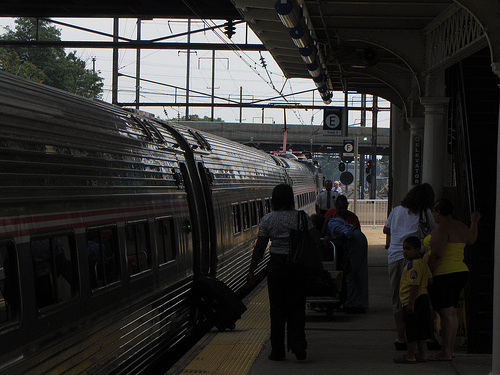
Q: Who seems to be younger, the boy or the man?
A: The boy is younger than the man.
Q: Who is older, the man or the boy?
A: The man is older than the boy.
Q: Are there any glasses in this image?
A: No, there are no glasses.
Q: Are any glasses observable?
A: No, there are no glasses.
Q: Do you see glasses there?
A: No, there are no glasses.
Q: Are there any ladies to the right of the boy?
A: Yes, there is a lady to the right of the boy.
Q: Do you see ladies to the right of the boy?
A: Yes, there is a lady to the right of the boy.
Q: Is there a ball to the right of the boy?
A: No, there is a lady to the right of the boy.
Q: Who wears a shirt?
A: The lady wears a shirt.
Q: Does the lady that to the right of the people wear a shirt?
A: Yes, the lady wears a shirt.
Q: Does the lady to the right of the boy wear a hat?
A: No, the lady wears a shirt.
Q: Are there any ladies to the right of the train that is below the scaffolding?
A: Yes, there is a lady to the right of the train.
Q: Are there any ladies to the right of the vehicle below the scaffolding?
A: Yes, there is a lady to the right of the train.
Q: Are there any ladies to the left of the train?
A: No, the lady is to the right of the train.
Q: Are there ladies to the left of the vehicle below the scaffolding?
A: No, the lady is to the right of the train.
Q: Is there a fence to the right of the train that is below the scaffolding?
A: No, there is a lady to the right of the train.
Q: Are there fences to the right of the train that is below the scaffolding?
A: No, there is a lady to the right of the train.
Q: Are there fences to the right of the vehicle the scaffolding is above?
A: No, there is a lady to the right of the train.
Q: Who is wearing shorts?
A: The lady is wearing shorts.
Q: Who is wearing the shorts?
A: The lady is wearing shorts.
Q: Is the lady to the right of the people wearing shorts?
A: Yes, the lady is wearing shorts.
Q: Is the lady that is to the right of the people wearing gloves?
A: No, the lady is wearing shorts.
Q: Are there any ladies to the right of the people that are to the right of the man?
A: Yes, there is a lady to the right of the people.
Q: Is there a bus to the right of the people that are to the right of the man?
A: No, there is a lady to the right of the people.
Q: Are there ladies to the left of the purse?
A: No, the lady is to the right of the purse.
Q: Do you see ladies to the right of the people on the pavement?
A: Yes, there is a lady to the right of the people.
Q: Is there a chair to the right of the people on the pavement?
A: No, there is a lady to the right of the people.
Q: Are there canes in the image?
A: No, there are no canes.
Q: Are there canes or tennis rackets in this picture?
A: No, there are no canes or tennis rackets.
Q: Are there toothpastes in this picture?
A: No, there are no toothpastes.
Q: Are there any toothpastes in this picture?
A: No, there are no toothpastes.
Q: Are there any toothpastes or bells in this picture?
A: No, there are no toothpastes or bells.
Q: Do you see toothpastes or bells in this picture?
A: No, there are no toothpastes or bells.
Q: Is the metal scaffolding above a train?
A: Yes, the scaffolding is above a train.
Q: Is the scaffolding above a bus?
A: No, the scaffolding is above a train.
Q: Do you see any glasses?
A: No, there are no glasses.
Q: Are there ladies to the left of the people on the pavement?
A: Yes, there is a lady to the left of the people.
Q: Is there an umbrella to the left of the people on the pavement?
A: No, there is a lady to the left of the people.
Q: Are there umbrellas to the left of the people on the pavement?
A: No, there is a lady to the left of the people.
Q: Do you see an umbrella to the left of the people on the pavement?
A: No, there is a lady to the left of the people.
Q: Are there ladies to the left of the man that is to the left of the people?
A: Yes, there is a lady to the left of the man.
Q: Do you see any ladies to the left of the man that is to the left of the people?
A: Yes, there is a lady to the left of the man.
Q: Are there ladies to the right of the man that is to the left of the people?
A: No, the lady is to the left of the man.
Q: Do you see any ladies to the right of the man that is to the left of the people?
A: No, the lady is to the left of the man.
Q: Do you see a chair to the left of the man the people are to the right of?
A: No, there is a lady to the left of the man.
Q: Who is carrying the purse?
A: The lady is carrying the purse.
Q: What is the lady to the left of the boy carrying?
A: The lady is carrying a purse.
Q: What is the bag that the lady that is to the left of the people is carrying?
A: The bag is a purse.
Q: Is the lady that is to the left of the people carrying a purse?
A: Yes, the lady is carrying a purse.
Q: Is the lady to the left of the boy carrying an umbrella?
A: No, the lady is carrying a purse.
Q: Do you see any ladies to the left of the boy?
A: Yes, there is a lady to the left of the boy.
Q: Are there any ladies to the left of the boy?
A: Yes, there is a lady to the left of the boy.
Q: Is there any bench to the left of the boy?
A: No, there is a lady to the left of the boy.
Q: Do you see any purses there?
A: Yes, there is a purse.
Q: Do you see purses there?
A: Yes, there is a purse.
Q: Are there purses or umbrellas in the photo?
A: Yes, there is a purse.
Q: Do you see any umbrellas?
A: No, there are no umbrellas.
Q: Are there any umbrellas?
A: No, there are no umbrellas.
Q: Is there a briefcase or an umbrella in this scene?
A: No, there are no umbrellas or briefcases.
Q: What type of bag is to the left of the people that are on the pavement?
A: The bag is a purse.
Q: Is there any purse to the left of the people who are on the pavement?
A: Yes, there is a purse to the left of the people.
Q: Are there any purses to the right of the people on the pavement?
A: No, the purse is to the left of the people.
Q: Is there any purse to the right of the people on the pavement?
A: No, the purse is to the left of the people.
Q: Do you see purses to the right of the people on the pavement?
A: No, the purse is to the left of the people.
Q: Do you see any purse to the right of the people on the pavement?
A: No, the purse is to the left of the people.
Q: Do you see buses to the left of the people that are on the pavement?
A: No, there is a purse to the left of the people.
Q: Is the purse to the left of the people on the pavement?
A: Yes, the purse is to the left of the people.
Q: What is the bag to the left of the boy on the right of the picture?
A: The bag is a purse.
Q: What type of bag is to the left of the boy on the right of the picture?
A: The bag is a purse.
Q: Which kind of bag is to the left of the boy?
A: The bag is a purse.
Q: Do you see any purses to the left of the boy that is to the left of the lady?
A: Yes, there is a purse to the left of the boy.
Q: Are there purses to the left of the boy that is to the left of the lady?
A: Yes, there is a purse to the left of the boy.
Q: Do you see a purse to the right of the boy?
A: No, the purse is to the left of the boy.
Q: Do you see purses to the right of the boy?
A: No, the purse is to the left of the boy.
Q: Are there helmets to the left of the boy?
A: No, there is a purse to the left of the boy.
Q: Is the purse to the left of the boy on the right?
A: Yes, the purse is to the left of the boy.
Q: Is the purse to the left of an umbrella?
A: No, the purse is to the left of the boy.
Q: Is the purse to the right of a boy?
A: No, the purse is to the left of a boy.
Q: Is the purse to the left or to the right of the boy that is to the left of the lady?
A: The purse is to the left of the boy.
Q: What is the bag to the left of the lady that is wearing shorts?
A: The bag is a purse.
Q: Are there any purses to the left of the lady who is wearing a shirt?
A: Yes, there is a purse to the left of the lady.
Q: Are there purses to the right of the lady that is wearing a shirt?
A: No, the purse is to the left of the lady.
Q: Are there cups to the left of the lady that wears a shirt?
A: No, there is a purse to the left of the lady.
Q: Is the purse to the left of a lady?
A: Yes, the purse is to the left of a lady.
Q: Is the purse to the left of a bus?
A: No, the purse is to the left of a lady.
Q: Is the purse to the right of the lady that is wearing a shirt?
A: No, the purse is to the left of the lady.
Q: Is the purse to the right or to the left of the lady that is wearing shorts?
A: The purse is to the left of the lady.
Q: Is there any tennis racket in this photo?
A: No, there are no rackets.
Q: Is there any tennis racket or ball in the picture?
A: No, there are no rackets or balls.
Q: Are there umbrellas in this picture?
A: No, there are no umbrellas.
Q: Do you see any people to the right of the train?
A: Yes, there are people to the right of the train.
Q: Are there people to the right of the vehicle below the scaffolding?
A: Yes, there are people to the right of the train.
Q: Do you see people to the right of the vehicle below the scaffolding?
A: Yes, there are people to the right of the train.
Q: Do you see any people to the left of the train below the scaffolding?
A: No, the people are to the right of the train.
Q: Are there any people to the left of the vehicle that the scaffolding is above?
A: No, the people are to the right of the train.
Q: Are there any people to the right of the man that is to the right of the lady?
A: Yes, there are people to the right of the man.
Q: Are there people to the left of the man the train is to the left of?
A: No, the people are to the right of the man.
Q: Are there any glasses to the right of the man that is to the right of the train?
A: No, there are people to the right of the man.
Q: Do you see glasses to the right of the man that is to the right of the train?
A: No, there are people to the right of the man.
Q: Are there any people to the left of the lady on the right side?
A: Yes, there are people to the left of the lady.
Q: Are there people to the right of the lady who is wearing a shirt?
A: No, the people are to the left of the lady.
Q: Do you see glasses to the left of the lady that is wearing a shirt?
A: No, there are people to the left of the lady.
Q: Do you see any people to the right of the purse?
A: Yes, there are people to the right of the purse.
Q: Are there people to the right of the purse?
A: Yes, there are people to the right of the purse.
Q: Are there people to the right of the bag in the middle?
A: Yes, there are people to the right of the purse.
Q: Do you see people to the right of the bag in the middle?
A: Yes, there are people to the right of the purse.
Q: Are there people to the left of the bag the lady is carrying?
A: No, the people are to the right of the purse.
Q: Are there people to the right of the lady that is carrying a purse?
A: Yes, there are people to the right of the lady.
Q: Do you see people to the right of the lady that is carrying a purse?
A: Yes, there are people to the right of the lady.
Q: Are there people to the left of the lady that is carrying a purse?
A: No, the people are to the right of the lady.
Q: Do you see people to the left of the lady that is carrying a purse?
A: No, the people are to the right of the lady.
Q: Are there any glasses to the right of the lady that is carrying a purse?
A: No, there are people to the right of the lady.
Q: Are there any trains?
A: Yes, there is a train.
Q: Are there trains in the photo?
A: Yes, there is a train.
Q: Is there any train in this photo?
A: Yes, there is a train.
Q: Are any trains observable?
A: Yes, there is a train.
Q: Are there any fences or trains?
A: Yes, there is a train.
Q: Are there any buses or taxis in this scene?
A: No, there are no buses or taxis.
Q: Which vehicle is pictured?
A: The vehicle is a train.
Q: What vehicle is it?
A: The vehicle is a train.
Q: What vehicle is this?
A: This is a train.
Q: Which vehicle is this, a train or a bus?
A: This is a train.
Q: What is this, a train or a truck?
A: This is a train.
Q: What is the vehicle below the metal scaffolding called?
A: The vehicle is a train.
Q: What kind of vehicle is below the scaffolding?
A: The vehicle is a train.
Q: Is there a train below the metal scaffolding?
A: Yes, there is a train below the scaffolding.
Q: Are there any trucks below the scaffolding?
A: No, there is a train below the scaffolding.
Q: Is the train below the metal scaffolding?
A: Yes, the train is below the scaffolding.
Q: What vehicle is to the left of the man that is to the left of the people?
A: The vehicle is a train.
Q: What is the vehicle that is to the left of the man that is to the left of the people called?
A: The vehicle is a train.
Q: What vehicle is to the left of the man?
A: The vehicle is a train.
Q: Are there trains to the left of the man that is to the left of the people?
A: Yes, there is a train to the left of the man.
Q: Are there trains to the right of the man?
A: No, the train is to the left of the man.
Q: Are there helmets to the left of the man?
A: No, there is a train to the left of the man.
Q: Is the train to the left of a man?
A: Yes, the train is to the left of a man.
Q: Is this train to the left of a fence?
A: No, the train is to the left of a man.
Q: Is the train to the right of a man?
A: No, the train is to the left of a man.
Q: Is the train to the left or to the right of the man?
A: The train is to the left of the man.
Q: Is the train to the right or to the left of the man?
A: The train is to the left of the man.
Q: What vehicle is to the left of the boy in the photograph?
A: The vehicle is a train.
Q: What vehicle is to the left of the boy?
A: The vehicle is a train.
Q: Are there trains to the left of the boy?
A: Yes, there is a train to the left of the boy.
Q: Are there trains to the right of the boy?
A: No, the train is to the left of the boy.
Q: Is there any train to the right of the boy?
A: No, the train is to the left of the boy.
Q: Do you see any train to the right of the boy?
A: No, the train is to the left of the boy.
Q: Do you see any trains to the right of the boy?
A: No, the train is to the left of the boy.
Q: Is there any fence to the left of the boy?
A: No, there is a train to the left of the boy.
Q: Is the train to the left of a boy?
A: Yes, the train is to the left of a boy.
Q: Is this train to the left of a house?
A: No, the train is to the left of a boy.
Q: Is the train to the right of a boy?
A: No, the train is to the left of a boy.